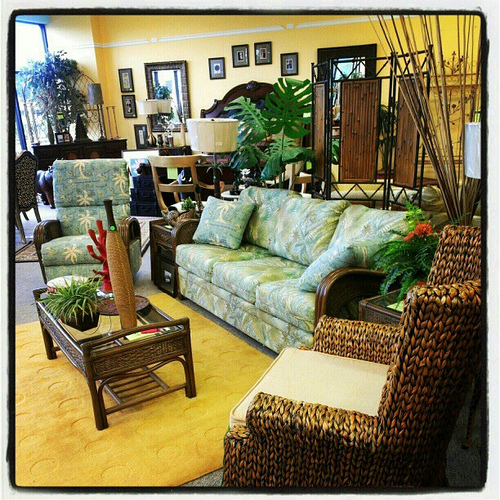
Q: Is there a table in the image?
A: Yes, there is a table.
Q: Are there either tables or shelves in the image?
A: Yes, there is a table.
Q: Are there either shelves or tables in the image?
A: Yes, there is a table.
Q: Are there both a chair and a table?
A: Yes, there are both a table and a chair.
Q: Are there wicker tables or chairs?
A: Yes, there is a wicker table.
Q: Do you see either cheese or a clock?
A: No, there are no clocks or cheese.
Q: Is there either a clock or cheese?
A: No, there are no clocks or cheese.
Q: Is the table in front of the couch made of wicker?
A: Yes, the table is made of wicker.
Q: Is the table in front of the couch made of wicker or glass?
A: The table is made of wicker.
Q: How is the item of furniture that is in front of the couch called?
A: The piece of furniture is a table.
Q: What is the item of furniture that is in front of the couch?
A: The piece of furniture is a table.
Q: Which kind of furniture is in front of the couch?
A: The piece of furniture is a table.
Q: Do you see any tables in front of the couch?
A: Yes, there is a table in front of the couch.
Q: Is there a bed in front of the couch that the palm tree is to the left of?
A: No, there is a table in front of the couch.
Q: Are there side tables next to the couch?
A: Yes, there is a side table next to the couch.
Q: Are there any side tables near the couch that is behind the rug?
A: Yes, there is a side table near the couch.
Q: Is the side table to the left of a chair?
A: Yes, the side table is to the left of a chair.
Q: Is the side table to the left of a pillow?
A: No, the side table is to the left of a chair.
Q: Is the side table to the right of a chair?
A: No, the side table is to the left of a chair.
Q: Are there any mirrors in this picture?
A: Yes, there is a mirror.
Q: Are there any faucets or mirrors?
A: Yes, there is a mirror.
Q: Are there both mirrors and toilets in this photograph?
A: No, there is a mirror but no toilets.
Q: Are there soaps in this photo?
A: No, there are no soaps.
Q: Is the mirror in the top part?
A: Yes, the mirror is in the top of the image.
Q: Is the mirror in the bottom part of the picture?
A: No, the mirror is in the top of the image.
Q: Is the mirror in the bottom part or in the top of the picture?
A: The mirror is in the top of the image.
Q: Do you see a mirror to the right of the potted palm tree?
A: Yes, there is a mirror to the right of the palm tree.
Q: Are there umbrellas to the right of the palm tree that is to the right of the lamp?
A: No, there is a mirror to the right of the palm tree.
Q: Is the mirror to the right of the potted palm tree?
A: Yes, the mirror is to the right of the palm.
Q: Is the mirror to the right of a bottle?
A: No, the mirror is to the right of the palm.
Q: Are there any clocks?
A: No, there are no clocks.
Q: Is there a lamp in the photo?
A: Yes, there is a lamp.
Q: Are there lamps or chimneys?
A: Yes, there is a lamp.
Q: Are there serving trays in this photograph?
A: No, there are no serving trays.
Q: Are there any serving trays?
A: No, there are no serving trays.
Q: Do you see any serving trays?
A: No, there are no serving trays.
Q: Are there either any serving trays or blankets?
A: No, there are no serving trays or blankets.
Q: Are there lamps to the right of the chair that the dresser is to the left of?
A: Yes, there is a lamp to the right of the chair.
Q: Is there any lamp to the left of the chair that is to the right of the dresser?
A: No, the lamp is to the right of the chair.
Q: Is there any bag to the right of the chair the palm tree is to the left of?
A: No, there is a lamp to the right of the chair.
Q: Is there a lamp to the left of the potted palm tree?
A: Yes, there is a lamp to the left of the palm tree.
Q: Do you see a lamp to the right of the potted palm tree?
A: No, the lamp is to the left of the palm tree.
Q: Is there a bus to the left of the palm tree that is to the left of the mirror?
A: No, there is a lamp to the left of the palm.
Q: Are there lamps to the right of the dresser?
A: Yes, there is a lamp to the right of the dresser.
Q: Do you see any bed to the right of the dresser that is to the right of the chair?
A: No, there is a lamp to the right of the dresser.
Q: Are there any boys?
A: No, there are no boys.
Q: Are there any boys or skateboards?
A: No, there are no boys or skateboards.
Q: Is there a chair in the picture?
A: Yes, there is a chair.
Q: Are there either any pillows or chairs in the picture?
A: Yes, there is a chair.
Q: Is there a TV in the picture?
A: No, there are no televisions.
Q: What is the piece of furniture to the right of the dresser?
A: The piece of furniture is a chair.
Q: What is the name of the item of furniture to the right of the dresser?
A: The piece of furniture is a chair.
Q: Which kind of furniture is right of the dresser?
A: The piece of furniture is a chair.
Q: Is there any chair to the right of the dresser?
A: Yes, there is a chair to the right of the dresser.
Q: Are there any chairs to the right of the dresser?
A: Yes, there is a chair to the right of the dresser.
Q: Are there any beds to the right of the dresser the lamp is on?
A: No, there is a chair to the right of the dresser.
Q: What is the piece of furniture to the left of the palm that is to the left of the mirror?
A: The piece of furniture is a chair.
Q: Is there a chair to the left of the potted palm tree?
A: Yes, there is a chair to the left of the palm.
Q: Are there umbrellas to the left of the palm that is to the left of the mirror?
A: No, there is a chair to the left of the palm.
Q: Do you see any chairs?
A: Yes, there is a chair.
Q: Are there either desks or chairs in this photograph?
A: Yes, there is a chair.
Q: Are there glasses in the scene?
A: No, there are no glasses.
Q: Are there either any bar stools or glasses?
A: No, there are no glasses or bar stools.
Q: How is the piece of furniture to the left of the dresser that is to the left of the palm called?
A: The piece of furniture is a chair.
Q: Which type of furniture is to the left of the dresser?
A: The piece of furniture is a chair.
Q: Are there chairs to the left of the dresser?
A: Yes, there is a chair to the left of the dresser.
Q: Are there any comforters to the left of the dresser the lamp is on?
A: No, there is a chair to the left of the dresser.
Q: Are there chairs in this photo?
A: Yes, there is a chair.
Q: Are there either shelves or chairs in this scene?
A: Yes, there is a chair.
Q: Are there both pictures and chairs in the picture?
A: Yes, there are both a chair and a picture.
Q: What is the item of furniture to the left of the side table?
A: The piece of furniture is a chair.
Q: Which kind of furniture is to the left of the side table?
A: The piece of furniture is a chair.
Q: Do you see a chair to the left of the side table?
A: Yes, there is a chair to the left of the side table.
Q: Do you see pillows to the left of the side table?
A: No, there is a chair to the left of the side table.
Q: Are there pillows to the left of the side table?
A: No, there is a chair to the left of the side table.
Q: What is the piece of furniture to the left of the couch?
A: The piece of furniture is a chair.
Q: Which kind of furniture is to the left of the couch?
A: The piece of furniture is a chair.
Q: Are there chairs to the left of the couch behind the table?
A: Yes, there is a chair to the left of the couch.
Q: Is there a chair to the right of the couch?
A: No, the chair is to the left of the couch.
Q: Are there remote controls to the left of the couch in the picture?
A: No, there is a chair to the left of the couch.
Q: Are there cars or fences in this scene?
A: No, there are no fences or cars.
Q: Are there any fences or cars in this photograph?
A: No, there are no fences or cars.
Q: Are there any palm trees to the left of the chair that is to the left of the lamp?
A: Yes, there is a palm tree to the left of the chair.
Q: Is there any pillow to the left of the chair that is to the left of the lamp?
A: No, there is a palm tree to the left of the chair.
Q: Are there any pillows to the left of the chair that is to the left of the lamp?
A: No, there is a palm tree to the left of the chair.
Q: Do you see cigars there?
A: No, there are no cigars.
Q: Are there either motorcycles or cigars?
A: No, there are no cigars or motorcycles.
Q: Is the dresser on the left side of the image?
A: Yes, the dresser is on the left of the image.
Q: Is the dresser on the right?
A: No, the dresser is on the left of the image.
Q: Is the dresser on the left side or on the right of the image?
A: The dresser is on the left of the image.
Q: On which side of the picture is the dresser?
A: The dresser is on the left of the image.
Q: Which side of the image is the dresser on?
A: The dresser is on the left of the image.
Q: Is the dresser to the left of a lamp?
A: Yes, the dresser is to the left of a lamp.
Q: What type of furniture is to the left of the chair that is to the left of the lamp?
A: The piece of furniture is a dresser.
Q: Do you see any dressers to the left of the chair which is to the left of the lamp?
A: Yes, there is a dresser to the left of the chair.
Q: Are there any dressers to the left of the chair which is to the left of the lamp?
A: Yes, there is a dresser to the left of the chair.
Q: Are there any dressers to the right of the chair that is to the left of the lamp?
A: No, the dresser is to the left of the chair.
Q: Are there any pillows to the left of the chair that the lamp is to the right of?
A: No, there is a dresser to the left of the chair.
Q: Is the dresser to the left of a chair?
A: Yes, the dresser is to the left of a chair.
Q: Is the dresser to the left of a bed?
A: No, the dresser is to the left of a chair.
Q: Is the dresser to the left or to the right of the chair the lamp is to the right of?
A: The dresser is to the left of the chair.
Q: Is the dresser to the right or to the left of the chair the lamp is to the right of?
A: The dresser is to the left of the chair.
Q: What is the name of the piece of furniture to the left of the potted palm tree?
A: The piece of furniture is a dresser.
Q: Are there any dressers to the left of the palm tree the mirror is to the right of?
A: Yes, there is a dresser to the left of the palm.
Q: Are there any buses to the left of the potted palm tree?
A: No, there is a dresser to the left of the palm.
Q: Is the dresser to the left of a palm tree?
A: Yes, the dresser is to the left of a palm tree.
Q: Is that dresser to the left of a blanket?
A: No, the dresser is to the left of a palm tree.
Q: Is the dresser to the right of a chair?
A: Yes, the dresser is to the right of a chair.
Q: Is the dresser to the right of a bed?
A: No, the dresser is to the right of a chair.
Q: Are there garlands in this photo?
A: No, there are no garlands.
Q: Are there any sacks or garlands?
A: No, there are no garlands or sacks.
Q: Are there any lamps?
A: Yes, there is a lamp.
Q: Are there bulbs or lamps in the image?
A: Yes, there is a lamp.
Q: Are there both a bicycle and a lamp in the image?
A: No, there is a lamp but no bicycles.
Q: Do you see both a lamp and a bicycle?
A: No, there is a lamp but no bicycles.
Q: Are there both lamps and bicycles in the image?
A: No, there is a lamp but no bicycles.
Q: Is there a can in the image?
A: No, there are no cans.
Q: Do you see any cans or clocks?
A: No, there are no cans or clocks.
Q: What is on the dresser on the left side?
A: The lamp is on the dresser.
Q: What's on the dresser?
A: The lamp is on the dresser.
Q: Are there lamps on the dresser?
A: Yes, there is a lamp on the dresser.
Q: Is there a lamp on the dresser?
A: Yes, there is a lamp on the dresser.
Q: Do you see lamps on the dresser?
A: Yes, there is a lamp on the dresser.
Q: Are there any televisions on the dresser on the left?
A: No, there is a lamp on the dresser.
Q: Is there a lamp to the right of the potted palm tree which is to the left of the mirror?
A: No, the lamp is to the left of the palm.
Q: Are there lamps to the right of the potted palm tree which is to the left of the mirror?
A: No, the lamp is to the left of the palm.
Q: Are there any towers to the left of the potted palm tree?
A: No, there is a lamp to the left of the palm.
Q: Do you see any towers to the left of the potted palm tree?
A: No, there is a lamp to the left of the palm.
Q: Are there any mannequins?
A: No, there are no mannequins.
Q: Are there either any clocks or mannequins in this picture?
A: No, there are no mannequins or clocks.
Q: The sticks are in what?
A: The sticks are in the vase.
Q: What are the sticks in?
A: The sticks are in the vase.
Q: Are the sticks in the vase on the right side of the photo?
A: Yes, the sticks are in the vase.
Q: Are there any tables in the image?
A: Yes, there is a table.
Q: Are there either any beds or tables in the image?
A: Yes, there is a table.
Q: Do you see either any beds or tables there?
A: Yes, there is a table.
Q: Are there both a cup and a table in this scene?
A: No, there is a table but no cups.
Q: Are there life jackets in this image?
A: No, there are no life jackets.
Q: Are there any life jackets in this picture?
A: No, there are no life jackets.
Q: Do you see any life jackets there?
A: No, there are no life jackets.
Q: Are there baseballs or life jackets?
A: No, there are no life jackets or baseballs.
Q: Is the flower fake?
A: Yes, the flower is fake.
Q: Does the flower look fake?
A: Yes, the flower is fake.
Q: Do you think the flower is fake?
A: Yes, the flower is fake.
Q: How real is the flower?
A: The flower is fake.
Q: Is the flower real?
A: No, the flower is fake.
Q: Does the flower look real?
A: No, the flower is fake.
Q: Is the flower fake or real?
A: The flower is fake.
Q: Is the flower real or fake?
A: The flower is fake.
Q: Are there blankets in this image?
A: No, there are no blankets.